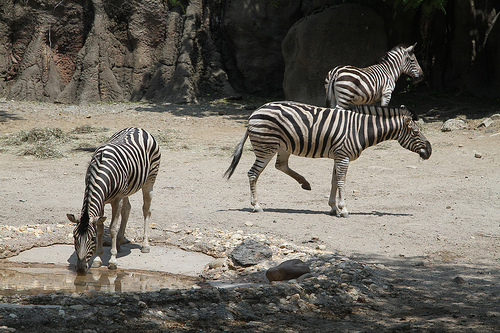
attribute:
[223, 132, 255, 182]
tail — long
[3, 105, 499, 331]
ground — packed down, sandy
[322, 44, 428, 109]
moving — walking, facing away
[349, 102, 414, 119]
mane — black, white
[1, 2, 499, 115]
rock — formed, old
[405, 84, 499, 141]
patches — sparse, green, grass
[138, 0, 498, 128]
shadow — predicting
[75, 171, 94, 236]
black — short, coarse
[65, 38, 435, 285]
zebra — black, white